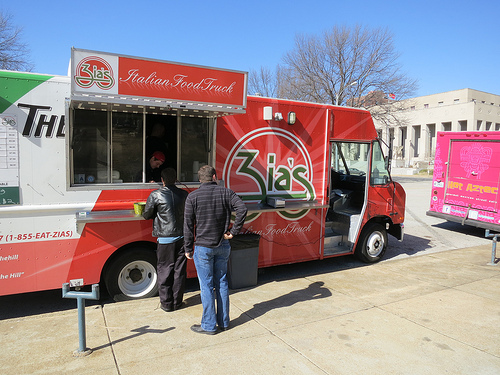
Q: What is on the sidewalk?
A: People.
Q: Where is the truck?
A: Curb.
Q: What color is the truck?
A: Red.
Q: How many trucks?
A: 2.